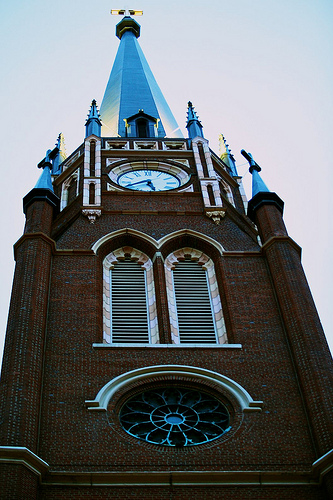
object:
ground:
[251, 92, 289, 134]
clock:
[103, 160, 195, 191]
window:
[85, 364, 264, 447]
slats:
[173, 257, 217, 343]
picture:
[0, 0, 333, 500]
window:
[60, 168, 80, 212]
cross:
[240, 149, 262, 174]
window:
[91, 227, 242, 348]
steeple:
[99, 9, 185, 139]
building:
[0, 9, 333, 500]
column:
[0, 165, 333, 500]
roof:
[23, 8, 285, 239]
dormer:
[90, 227, 226, 252]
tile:
[163, 246, 228, 347]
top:
[108, 6, 146, 13]